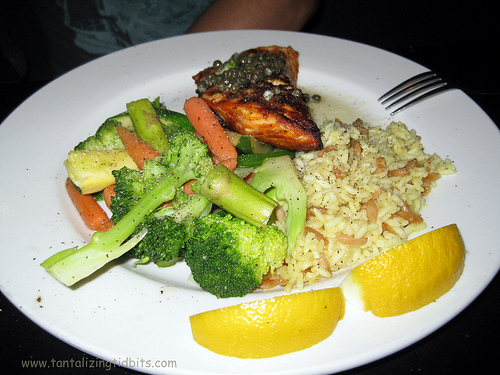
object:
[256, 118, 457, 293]
rice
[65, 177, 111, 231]
carrot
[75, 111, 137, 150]
brocccoli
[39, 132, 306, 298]
vegetable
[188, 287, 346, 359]
lemon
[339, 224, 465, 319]
lemon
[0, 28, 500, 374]
dish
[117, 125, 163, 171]
carrots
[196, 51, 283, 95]
capers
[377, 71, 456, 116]
fork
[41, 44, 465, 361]
meal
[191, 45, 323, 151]
salmon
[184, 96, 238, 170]
baby carrots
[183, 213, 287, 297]
broccoli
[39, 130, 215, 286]
broccoli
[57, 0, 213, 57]
person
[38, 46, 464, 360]
food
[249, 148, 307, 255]
broccoli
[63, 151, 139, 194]
sqaush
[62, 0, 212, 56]
shirt